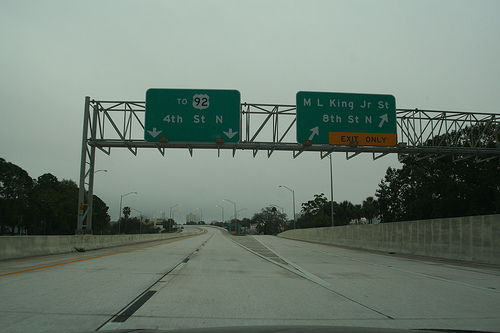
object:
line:
[54, 236, 200, 265]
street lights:
[118, 191, 137, 235]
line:
[97, 256, 192, 333]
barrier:
[290, 212, 500, 266]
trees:
[371, 115, 498, 220]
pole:
[279, 186, 296, 229]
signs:
[143, 87, 242, 144]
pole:
[77, 96, 88, 230]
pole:
[86, 102, 100, 232]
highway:
[2, 222, 497, 333]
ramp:
[194, 227, 220, 236]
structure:
[77, 88, 500, 239]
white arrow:
[378, 113, 389, 127]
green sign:
[297, 90, 396, 145]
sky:
[1, 0, 500, 217]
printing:
[143, 87, 243, 144]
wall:
[277, 214, 500, 266]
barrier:
[0, 235, 89, 259]